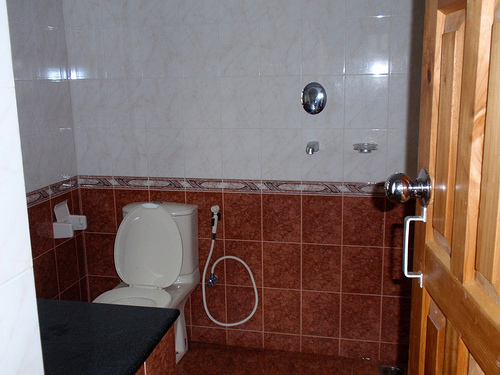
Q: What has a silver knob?
A: A brown door.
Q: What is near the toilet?
A: The red tile wall.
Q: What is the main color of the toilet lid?
A: White.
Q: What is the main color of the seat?
A: White.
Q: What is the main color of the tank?
A: White.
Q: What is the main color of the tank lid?
A: White.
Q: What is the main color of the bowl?
A: White.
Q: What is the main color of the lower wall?
A: Red.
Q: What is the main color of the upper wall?
A: White.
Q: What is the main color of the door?
A: Brown.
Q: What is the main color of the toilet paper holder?
A: White.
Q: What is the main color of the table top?
A: Black.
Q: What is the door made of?
A: Wood.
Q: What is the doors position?
A: Open.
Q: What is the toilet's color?
A: White.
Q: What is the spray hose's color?
A: White.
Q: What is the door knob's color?
A: Silver and white.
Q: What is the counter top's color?
A: Black.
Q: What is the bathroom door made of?
A: Wood.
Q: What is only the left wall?
A: Toilet paper holder.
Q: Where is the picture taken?
A: Bathroom.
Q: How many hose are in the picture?
A: One.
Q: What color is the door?
A: Brown.